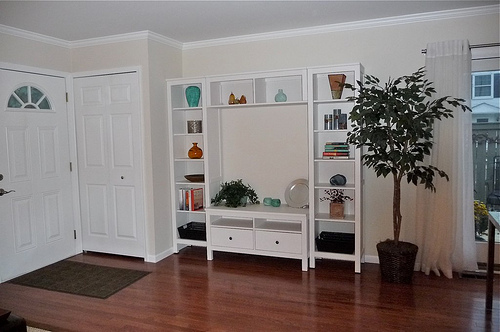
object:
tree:
[333, 66, 473, 246]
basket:
[376, 239, 419, 283]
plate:
[285, 179, 309, 208]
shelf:
[205, 203, 309, 218]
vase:
[185, 86, 201, 108]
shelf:
[173, 107, 202, 110]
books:
[322, 156, 349, 160]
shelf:
[315, 158, 355, 162]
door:
[0, 68, 80, 285]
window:
[8, 84, 54, 110]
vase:
[188, 143, 203, 159]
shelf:
[174, 157, 204, 161]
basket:
[315, 231, 355, 255]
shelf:
[315, 251, 355, 260]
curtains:
[413, 38, 478, 280]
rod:
[422, 42, 499, 53]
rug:
[7, 258, 153, 300]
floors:
[0, 243, 497, 329]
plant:
[320, 189, 353, 203]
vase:
[330, 203, 345, 219]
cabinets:
[208, 201, 309, 273]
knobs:
[228, 237, 232, 240]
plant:
[211, 179, 260, 209]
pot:
[240, 196, 247, 207]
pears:
[228, 92, 235, 105]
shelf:
[209, 100, 307, 108]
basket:
[177, 221, 207, 241]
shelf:
[178, 239, 207, 247]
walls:
[0, 4, 498, 264]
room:
[0, 0, 500, 332]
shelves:
[165, 63, 366, 274]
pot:
[328, 74, 347, 99]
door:
[71, 67, 147, 259]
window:
[471, 69, 500, 243]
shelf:
[314, 99, 348, 103]